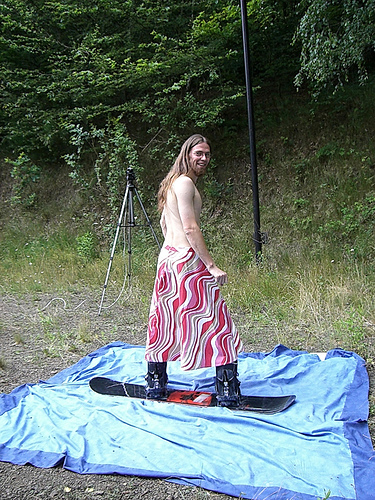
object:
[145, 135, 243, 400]
man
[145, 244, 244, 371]
skirt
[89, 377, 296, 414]
snowboard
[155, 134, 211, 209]
hair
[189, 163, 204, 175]
beard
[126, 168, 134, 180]
camera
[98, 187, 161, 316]
tripod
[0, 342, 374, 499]
tarp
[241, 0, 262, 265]
pole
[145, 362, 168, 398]
snowboard boot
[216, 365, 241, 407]
snowboard boot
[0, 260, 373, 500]
ground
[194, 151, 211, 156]
glasses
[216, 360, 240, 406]
foot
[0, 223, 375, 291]
grass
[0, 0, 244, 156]
tree